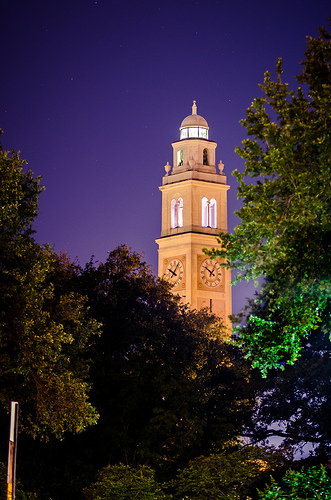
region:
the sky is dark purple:
[59, 102, 147, 237]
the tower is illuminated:
[152, 96, 259, 393]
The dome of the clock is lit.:
[179, 98, 215, 141]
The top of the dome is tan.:
[175, 93, 216, 128]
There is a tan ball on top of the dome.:
[189, 96, 202, 104]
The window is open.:
[196, 145, 214, 168]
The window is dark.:
[201, 147, 211, 167]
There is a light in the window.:
[164, 191, 185, 231]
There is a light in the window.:
[201, 193, 219, 233]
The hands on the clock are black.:
[167, 263, 181, 280]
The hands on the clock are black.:
[204, 264, 216, 278]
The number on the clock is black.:
[172, 260, 177, 266]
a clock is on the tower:
[165, 259, 185, 292]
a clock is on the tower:
[202, 255, 223, 288]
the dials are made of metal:
[168, 263, 178, 279]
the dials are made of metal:
[204, 263, 216, 279]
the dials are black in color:
[167, 262, 180, 280]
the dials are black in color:
[204, 263, 217, 277]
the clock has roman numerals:
[166, 259, 185, 289]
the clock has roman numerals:
[200, 256, 226, 291]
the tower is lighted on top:
[180, 124, 209, 142]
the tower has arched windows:
[202, 195, 218, 226]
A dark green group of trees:
[3, 147, 252, 498]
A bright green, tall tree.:
[204, 28, 329, 498]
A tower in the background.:
[154, 96, 230, 342]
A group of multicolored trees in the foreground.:
[0, 27, 330, 498]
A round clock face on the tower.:
[197, 256, 223, 289]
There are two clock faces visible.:
[162, 257, 225, 292]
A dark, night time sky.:
[0, 1, 328, 268]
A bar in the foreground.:
[7, 400, 20, 498]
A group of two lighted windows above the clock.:
[197, 193, 226, 292]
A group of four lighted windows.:
[167, 195, 217, 232]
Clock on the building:
[159, 256, 187, 286]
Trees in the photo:
[128, 351, 215, 443]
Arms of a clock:
[207, 264, 220, 278]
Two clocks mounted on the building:
[156, 256, 224, 290]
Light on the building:
[164, 194, 218, 228]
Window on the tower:
[197, 199, 220, 229]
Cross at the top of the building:
[184, 92, 207, 115]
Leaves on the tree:
[267, 260, 305, 320]